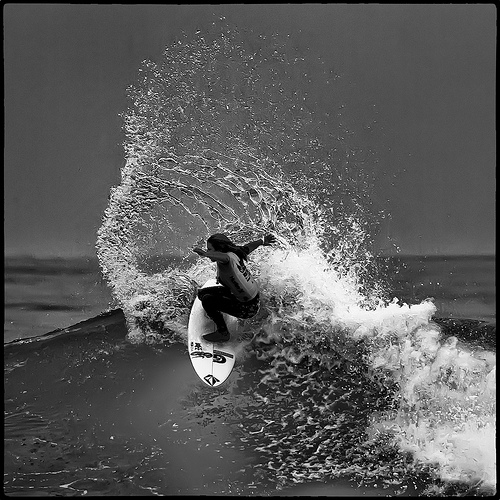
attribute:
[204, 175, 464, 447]
water — white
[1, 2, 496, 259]
sky — blue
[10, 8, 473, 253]
sky — blue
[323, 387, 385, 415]
waves — white, blue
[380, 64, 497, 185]
clouds — dark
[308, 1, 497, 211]
sky — blue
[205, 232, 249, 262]
black hair — long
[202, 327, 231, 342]
shoe — gray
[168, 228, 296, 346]
woman — concentrating, surfing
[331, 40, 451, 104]
sky — blue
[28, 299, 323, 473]
waves — blue, white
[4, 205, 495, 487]
waves — blue, white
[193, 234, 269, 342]
person — young, surfing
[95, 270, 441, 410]
waves — white, blue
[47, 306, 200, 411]
waves — white, blue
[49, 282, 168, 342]
waves — white , blue 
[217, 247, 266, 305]
top — grey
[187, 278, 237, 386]
surfboard — white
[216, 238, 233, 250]
hair — long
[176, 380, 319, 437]
water — crashing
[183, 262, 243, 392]
surfboard — white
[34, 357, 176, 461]
water — splashing 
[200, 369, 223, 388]
logo — volcom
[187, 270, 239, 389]
surfboard — white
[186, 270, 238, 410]
surfboard — white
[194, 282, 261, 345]
pants — black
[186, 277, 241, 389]
surfboard — white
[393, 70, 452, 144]
sky — blue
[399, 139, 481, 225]
cloud — white